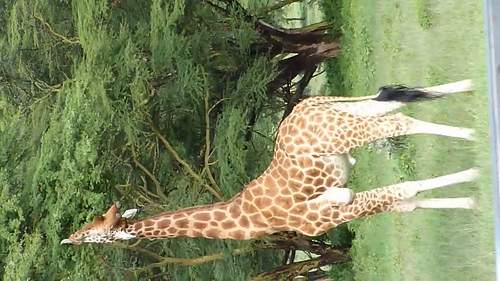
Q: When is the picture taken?
A: Daytime.